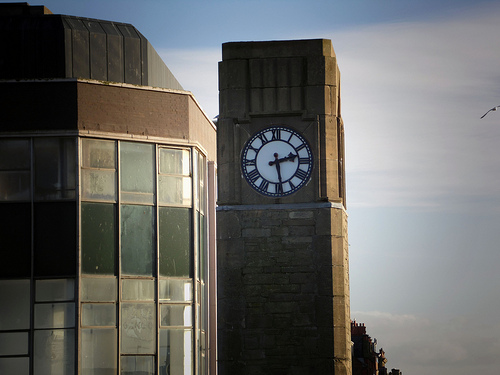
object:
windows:
[80, 278, 117, 326]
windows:
[79, 140, 117, 204]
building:
[0, 2, 354, 375]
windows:
[118, 204, 156, 278]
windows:
[158, 145, 194, 208]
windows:
[118, 300, 156, 354]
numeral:
[271, 128, 281, 140]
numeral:
[287, 132, 295, 143]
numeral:
[295, 143, 306, 151]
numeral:
[300, 157, 310, 164]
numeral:
[294, 169, 307, 180]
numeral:
[288, 179, 296, 189]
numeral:
[274, 182, 283, 194]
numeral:
[259, 179, 269, 192]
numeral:
[248, 169, 260, 183]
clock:
[241, 127, 313, 198]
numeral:
[246, 159, 256, 166]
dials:
[268, 151, 299, 196]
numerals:
[257, 133, 268, 144]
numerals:
[248, 144, 258, 153]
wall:
[213, 222, 339, 372]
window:
[118, 138, 156, 204]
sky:
[26, 0, 497, 370]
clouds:
[158, 1, 499, 375]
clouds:
[351, 305, 498, 374]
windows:
[193, 283, 211, 373]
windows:
[81, 199, 118, 277]